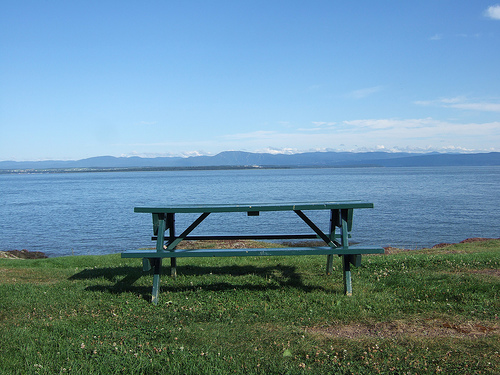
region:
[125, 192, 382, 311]
this is a bench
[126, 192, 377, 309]
the bench is empty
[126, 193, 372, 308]
the bench is wooden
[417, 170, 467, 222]
this is the water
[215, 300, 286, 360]
the grass is green in color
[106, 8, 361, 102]
the sky is clear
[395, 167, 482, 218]
the water is calm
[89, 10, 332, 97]
the sky is blue in color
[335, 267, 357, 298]
this is the leg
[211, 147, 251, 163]
mountain is at the far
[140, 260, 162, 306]
part of a stand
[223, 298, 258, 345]
part of a ground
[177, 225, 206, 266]
edge of a becnch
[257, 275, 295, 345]
part of a ground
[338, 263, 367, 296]
part of a stand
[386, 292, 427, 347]
part of a ground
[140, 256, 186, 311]
part of a stand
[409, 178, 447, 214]
part of a water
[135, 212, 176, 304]
Front left leg of bench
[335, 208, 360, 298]
Front right leg of bench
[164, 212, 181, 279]
Back left leg of bench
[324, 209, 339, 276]
Back right leg of bench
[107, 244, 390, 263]
Front seat of bench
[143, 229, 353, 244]
Back seat of bench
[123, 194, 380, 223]
Table top of bench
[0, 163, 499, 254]
Blue body of water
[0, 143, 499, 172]
Mountains in the distance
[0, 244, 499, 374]
Green grass around bench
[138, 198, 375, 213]
The top of the bench.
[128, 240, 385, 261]
The sitting area of the bench furthest away from the water.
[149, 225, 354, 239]
The sitting area of the bench closest to the water.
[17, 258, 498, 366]
The grass area where the bench is.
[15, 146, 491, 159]
The mountains in the distance.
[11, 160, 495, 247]
The water between the bench and the mountains.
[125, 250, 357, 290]
The feet of the bench.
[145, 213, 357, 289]
The legs of the bench.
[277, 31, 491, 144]
The white clouds in the sky.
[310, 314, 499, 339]
The dirt in the grass area.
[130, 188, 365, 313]
the bench is green in color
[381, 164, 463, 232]
this is water beside the bench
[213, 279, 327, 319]
grass are on the ground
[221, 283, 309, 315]
the grass are green in color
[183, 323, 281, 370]
the grass are short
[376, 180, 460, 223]
the water is blue in color